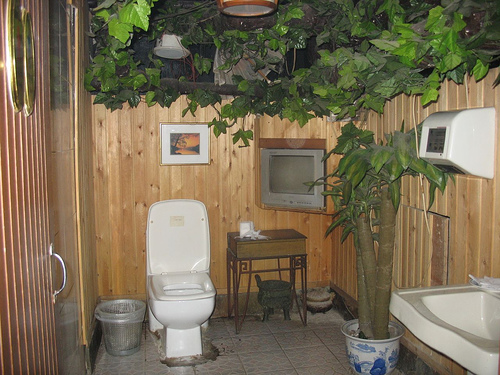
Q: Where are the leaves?
A: Along top of fence.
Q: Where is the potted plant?
A: On the floor.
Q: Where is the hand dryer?
A: Against the fence.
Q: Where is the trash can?
A: Corner left floor.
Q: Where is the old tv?
A: In the fence wall.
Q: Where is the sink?
A: Near right.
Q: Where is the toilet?
A: Straight forward.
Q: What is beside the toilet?
A: A small table in the room.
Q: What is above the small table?
A: A television set.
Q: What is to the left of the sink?
A: A potted tree.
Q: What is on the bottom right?
A: A sink.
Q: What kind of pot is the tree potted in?
A: A blue and white ceramic pot.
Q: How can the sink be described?
A: A white ceramic sink.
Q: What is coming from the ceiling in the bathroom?
A: Leaves.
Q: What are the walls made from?
A: Wood.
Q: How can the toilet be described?
A: A white toilet.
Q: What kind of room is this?
A: A bathroom.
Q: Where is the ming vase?
A: On the bathroom floor.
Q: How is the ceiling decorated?
A: With fake foliage.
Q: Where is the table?
A: Next to the toilet.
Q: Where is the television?
A: Mounted in the wall.